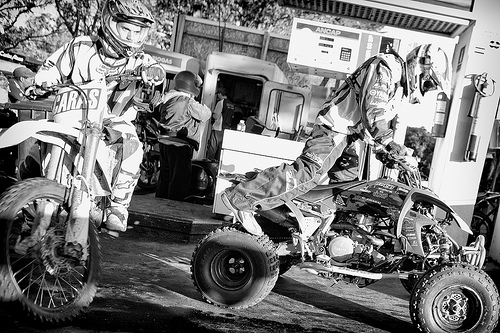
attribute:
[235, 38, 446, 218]
rider — standing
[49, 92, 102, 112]
sticker — black, white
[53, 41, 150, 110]
jacket — large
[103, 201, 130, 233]
shoes — white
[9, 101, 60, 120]
fence — wooden